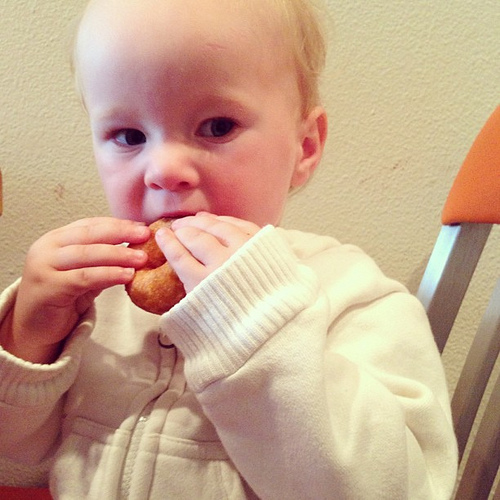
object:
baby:
[2, 1, 457, 499]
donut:
[122, 217, 187, 309]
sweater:
[0, 226, 459, 499]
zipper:
[113, 328, 181, 499]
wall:
[0, 3, 496, 251]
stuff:
[439, 102, 499, 225]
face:
[81, 65, 301, 239]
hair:
[268, 1, 328, 117]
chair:
[413, 101, 499, 492]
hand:
[154, 210, 262, 293]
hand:
[10, 213, 149, 350]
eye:
[193, 117, 239, 138]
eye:
[104, 127, 147, 146]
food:
[53, 184, 67, 196]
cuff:
[161, 225, 330, 396]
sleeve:
[154, 225, 457, 500]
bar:
[417, 223, 492, 352]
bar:
[450, 276, 499, 464]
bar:
[469, 371, 498, 497]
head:
[72, 3, 331, 230]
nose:
[144, 158, 200, 190]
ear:
[293, 107, 328, 189]